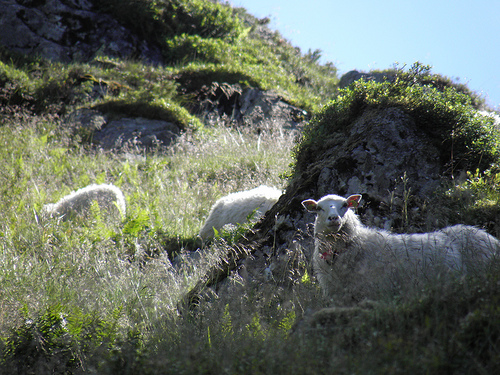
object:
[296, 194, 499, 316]
lamb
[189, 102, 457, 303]
rock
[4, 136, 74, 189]
grass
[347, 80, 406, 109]
grass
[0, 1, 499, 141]
hill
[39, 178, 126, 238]
lamb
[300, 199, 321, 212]
ears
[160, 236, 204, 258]
shadow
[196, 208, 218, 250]
neck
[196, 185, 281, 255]
lamb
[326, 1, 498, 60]
sky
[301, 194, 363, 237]
head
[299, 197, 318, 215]
left ear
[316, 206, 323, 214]
left eye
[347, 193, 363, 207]
right ear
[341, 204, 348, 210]
right eye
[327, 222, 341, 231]
mouth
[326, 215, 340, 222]
nose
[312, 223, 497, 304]
body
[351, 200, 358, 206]
tag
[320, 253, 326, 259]
red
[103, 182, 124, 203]
butt